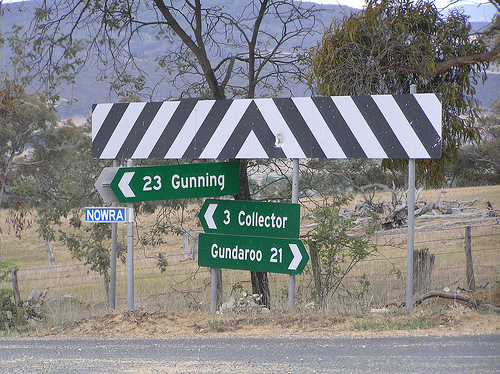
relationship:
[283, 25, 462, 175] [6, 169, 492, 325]
tree on ground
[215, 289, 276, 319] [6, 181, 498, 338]
rocks on ground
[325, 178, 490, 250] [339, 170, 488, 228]
pile of branches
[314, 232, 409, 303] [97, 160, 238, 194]
fence behind sign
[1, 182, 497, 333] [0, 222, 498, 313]
field behind fence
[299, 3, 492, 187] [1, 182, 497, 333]
trees behind field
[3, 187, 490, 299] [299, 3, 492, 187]
hill behind trees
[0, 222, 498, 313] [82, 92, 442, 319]
fence behind signs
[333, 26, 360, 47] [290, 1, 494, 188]
leaves are on tree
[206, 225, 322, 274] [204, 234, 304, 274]
gundaroo on sign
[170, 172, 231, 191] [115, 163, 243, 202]
gunning on sign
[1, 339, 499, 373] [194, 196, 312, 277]
road in front of signs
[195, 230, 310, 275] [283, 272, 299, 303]
sign on post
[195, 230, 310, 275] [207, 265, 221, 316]
sign on post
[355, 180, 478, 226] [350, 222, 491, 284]
sticks behind fence